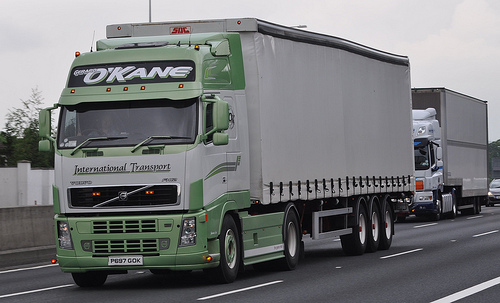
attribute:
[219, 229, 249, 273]
rim — silver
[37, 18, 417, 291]
semi trailer — whtie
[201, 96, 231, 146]
side mirror — green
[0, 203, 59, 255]
barrier wall — grey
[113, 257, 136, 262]
letters — black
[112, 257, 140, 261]
writing — black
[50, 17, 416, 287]
truck — white and green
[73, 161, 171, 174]
international transport — written, black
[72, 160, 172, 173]
international transport — black, written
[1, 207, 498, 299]
street — concrete, grey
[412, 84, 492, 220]
semi truck — white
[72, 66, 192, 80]
letters — white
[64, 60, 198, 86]
back ground — black